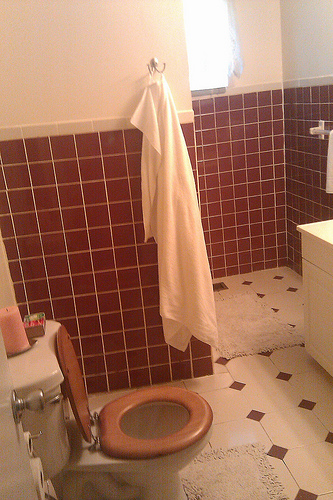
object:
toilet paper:
[30, 456, 51, 499]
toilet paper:
[23, 427, 33, 456]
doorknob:
[11, 387, 47, 425]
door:
[0, 325, 39, 497]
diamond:
[246, 409, 266, 423]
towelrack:
[309, 118, 332, 139]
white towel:
[146, 72, 217, 354]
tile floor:
[68, 266, 332, 499]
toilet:
[6, 318, 214, 500]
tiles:
[278, 436, 333, 498]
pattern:
[266, 443, 289, 461]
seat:
[46, 333, 221, 460]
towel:
[325, 128, 333, 195]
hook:
[146, 57, 166, 77]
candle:
[0, 305, 29, 353]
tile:
[23, 135, 54, 165]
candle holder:
[5, 338, 37, 360]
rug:
[208, 292, 304, 364]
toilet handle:
[46, 387, 71, 423]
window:
[185, 0, 229, 98]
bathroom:
[0, 0, 331, 500]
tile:
[195, 384, 257, 427]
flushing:
[45, 388, 70, 423]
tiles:
[237, 376, 308, 419]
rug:
[173, 438, 291, 497]